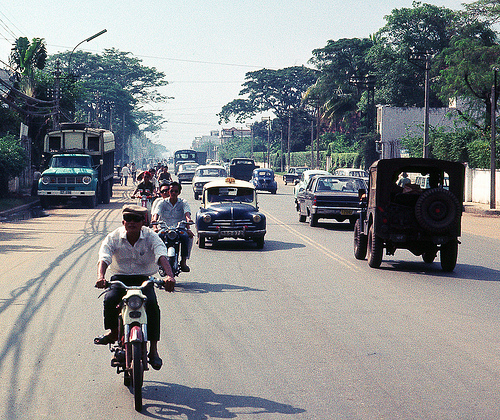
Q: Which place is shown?
A: It is a street.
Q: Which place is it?
A: It is a street.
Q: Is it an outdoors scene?
A: Yes, it is outdoors.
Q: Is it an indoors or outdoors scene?
A: It is outdoors.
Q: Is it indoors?
A: No, it is outdoors.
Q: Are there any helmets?
A: No, there are no helmets.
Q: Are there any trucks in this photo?
A: Yes, there is a truck.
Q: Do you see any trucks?
A: Yes, there is a truck.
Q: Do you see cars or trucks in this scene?
A: Yes, there is a truck.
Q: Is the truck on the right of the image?
A: No, the truck is on the left of the image.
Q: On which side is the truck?
A: The truck is on the left of the image.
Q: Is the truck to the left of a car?
A: Yes, the truck is to the left of a car.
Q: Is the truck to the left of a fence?
A: No, the truck is to the left of a car.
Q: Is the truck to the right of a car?
A: No, the truck is to the left of a car.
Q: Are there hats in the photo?
A: Yes, there is a hat.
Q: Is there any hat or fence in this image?
A: Yes, there is a hat.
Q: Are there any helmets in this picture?
A: No, there are no helmets.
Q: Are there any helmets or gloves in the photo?
A: No, there are no helmets or gloves.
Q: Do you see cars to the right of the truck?
A: Yes, there is a car to the right of the truck.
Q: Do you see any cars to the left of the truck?
A: No, the car is to the right of the truck.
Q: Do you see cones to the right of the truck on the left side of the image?
A: No, there is a car to the right of the truck.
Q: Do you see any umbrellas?
A: No, there are no umbrellas.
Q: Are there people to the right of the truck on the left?
A: Yes, there are people to the right of the truck.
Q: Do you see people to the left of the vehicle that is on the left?
A: No, the people are to the right of the truck.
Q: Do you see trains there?
A: No, there are no trains.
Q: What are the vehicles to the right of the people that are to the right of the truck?
A: The vehicles are cars.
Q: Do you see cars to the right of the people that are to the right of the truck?
A: Yes, there are cars to the right of the people.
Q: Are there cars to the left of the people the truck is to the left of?
A: No, the cars are to the right of the people.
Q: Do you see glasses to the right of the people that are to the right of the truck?
A: No, there are cars to the right of the people.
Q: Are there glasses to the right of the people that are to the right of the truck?
A: No, there are cars to the right of the people.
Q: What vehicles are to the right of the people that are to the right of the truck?
A: The vehicles are cars.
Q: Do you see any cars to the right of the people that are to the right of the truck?
A: Yes, there are cars to the right of the people.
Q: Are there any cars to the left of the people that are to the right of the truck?
A: No, the cars are to the right of the people.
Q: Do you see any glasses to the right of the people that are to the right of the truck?
A: No, there are cars to the right of the people.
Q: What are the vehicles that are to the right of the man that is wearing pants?
A: The vehicles are cars.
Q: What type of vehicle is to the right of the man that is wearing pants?
A: The vehicles are cars.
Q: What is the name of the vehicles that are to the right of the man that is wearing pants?
A: The vehicles are cars.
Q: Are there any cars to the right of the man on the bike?
A: Yes, there are cars to the right of the man.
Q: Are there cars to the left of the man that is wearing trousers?
A: No, the cars are to the right of the man.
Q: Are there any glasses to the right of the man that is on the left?
A: No, there are cars to the right of the man.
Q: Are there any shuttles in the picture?
A: No, there are no shuttles.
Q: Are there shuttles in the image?
A: No, there are no shuttles.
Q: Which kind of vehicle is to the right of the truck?
A: The vehicles are cars.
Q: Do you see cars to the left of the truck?
A: No, the cars are to the right of the truck.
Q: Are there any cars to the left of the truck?
A: No, the cars are to the right of the truck.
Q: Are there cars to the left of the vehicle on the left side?
A: No, the cars are to the right of the truck.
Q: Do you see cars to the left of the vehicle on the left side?
A: No, the cars are to the right of the truck.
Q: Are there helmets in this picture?
A: No, there are no helmets.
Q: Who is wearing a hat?
A: The man is wearing a hat.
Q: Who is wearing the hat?
A: The man is wearing a hat.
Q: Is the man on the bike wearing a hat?
A: Yes, the man is wearing a hat.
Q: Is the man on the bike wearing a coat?
A: No, the man is wearing a hat.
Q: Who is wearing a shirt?
A: The man is wearing a shirt.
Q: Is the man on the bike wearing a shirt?
A: Yes, the man is wearing a shirt.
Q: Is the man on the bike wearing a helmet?
A: No, the man is wearing a shirt.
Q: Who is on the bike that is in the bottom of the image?
A: The man is on the bike.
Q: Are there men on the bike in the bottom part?
A: Yes, there is a man on the bike.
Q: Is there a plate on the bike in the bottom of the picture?
A: No, there is a man on the bike.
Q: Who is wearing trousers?
A: The man is wearing trousers.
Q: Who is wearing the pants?
A: The man is wearing trousers.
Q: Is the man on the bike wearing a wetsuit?
A: No, the man is wearing a shirt.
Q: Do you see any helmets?
A: No, there are no helmets.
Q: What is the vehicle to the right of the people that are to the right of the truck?
A: The vehicle is a car.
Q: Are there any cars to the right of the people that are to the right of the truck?
A: Yes, there is a car to the right of the people.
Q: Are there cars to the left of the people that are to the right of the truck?
A: No, the car is to the right of the people.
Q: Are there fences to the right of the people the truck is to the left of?
A: No, there is a car to the right of the people.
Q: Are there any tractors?
A: No, there are no tractors.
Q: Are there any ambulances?
A: No, there are no ambulances.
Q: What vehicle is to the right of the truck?
A: The vehicle is a car.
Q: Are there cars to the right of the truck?
A: Yes, there is a car to the right of the truck.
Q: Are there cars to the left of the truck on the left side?
A: No, the car is to the right of the truck.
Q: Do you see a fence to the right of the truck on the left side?
A: No, there is a car to the right of the truck.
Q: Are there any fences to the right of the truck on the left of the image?
A: No, there is a car to the right of the truck.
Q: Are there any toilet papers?
A: No, there are no toilet papers.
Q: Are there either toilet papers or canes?
A: No, there are no toilet papers or canes.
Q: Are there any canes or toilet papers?
A: No, there are no toilet papers or canes.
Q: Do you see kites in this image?
A: No, there are no kites.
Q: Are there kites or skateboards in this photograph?
A: No, there are no kites or skateboards.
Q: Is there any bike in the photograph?
A: Yes, there is a bike.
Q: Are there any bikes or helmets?
A: Yes, there is a bike.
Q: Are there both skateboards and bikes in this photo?
A: No, there is a bike but no skateboards.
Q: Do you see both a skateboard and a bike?
A: No, there is a bike but no skateboards.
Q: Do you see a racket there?
A: No, there are no rackets.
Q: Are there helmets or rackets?
A: No, there are no rackets or helmets.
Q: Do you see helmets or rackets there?
A: No, there are no rackets or helmets.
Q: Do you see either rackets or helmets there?
A: No, there are no rackets or helmets.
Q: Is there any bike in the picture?
A: Yes, there is a bike.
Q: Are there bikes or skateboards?
A: Yes, there is a bike.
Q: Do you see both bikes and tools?
A: No, there is a bike but no tools.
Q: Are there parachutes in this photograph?
A: No, there are no parachutes.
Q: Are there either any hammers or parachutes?
A: No, there are no parachutes or hammers.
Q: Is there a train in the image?
A: No, there are no trains.